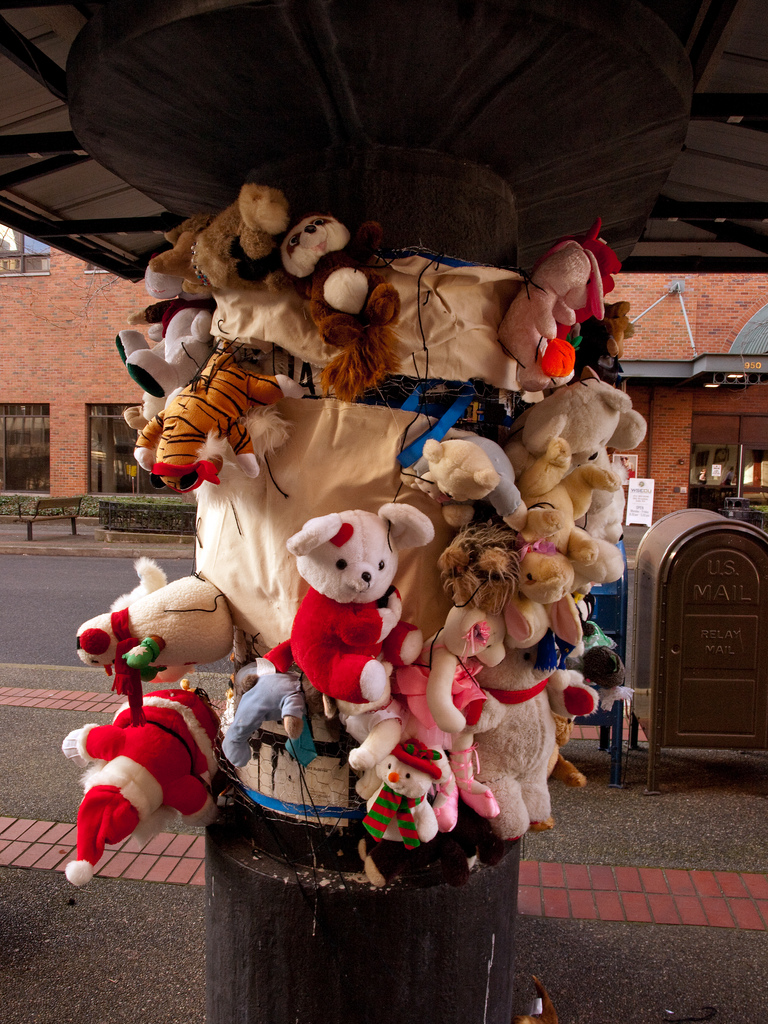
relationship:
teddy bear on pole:
[285, 498, 452, 702] [293, 142, 524, 263]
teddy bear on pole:
[280, 210, 409, 338] [168, 161, 533, 1022]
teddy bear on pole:
[285, 505, 400, 700] [168, 161, 533, 1022]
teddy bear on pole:
[405, 430, 520, 527] [168, 161, 533, 1022]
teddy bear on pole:
[529, 377, 643, 490] [168, 161, 533, 1022]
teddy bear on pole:
[466, 651, 592, 846] [168, 161, 533, 1022]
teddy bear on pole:
[285, 498, 452, 701] [168, 161, 533, 1022]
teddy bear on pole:
[285, 498, 452, 701] [184, 206, 564, 844]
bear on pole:
[162, 220, 761, 619] [296, 94, 508, 857]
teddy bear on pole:
[465, 650, 591, 846] [75, 4, 700, 1021]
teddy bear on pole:
[503, 446, 592, 613] [193, 160, 536, 828]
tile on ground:
[560, 826, 713, 918] [10, 527, 84, 637]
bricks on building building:
[5, 279, 133, 398] [5, 279, 133, 398]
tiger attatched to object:
[145, 343, 298, 482] [3, 27, 724, 1015]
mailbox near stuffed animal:
[624, 503, 761, 812] [49, 671, 232, 892]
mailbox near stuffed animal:
[624, 503, 761, 812] [354, 731, 445, 892]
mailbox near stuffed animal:
[624, 503, 761, 812] [254, 499, 441, 720]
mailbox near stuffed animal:
[624, 503, 761, 812] [403, 422, 532, 537]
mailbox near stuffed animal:
[624, 503, 761, 812] [123, 340, 308, 501]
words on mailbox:
[665, 534, 756, 631] [620, 512, 744, 795]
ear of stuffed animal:
[251, 498, 356, 581] [262, 495, 433, 707]